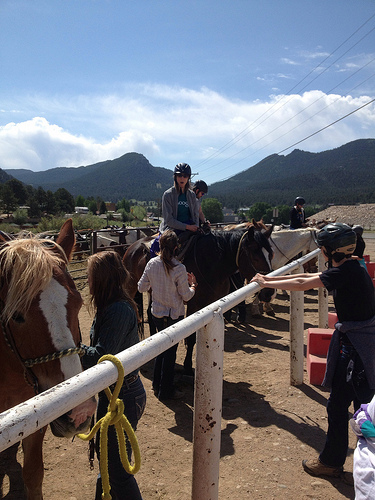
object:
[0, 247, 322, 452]
bar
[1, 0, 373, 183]
sky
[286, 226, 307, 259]
neck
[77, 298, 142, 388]
sweater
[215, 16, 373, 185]
power lines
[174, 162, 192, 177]
helmet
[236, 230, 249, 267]
harness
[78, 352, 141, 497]
rope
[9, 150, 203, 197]
mountain chain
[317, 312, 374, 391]
sweatshirt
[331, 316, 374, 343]
waist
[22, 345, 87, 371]
rope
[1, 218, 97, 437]
face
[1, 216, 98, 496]
horse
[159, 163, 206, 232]
woman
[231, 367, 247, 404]
rocks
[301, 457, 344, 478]
shoe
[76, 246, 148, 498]
lady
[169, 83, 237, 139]
cloud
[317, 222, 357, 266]
helmet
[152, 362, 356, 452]
shade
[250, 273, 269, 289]
hand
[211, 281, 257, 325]
rail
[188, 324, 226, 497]
pole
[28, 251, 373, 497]
ground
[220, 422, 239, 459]
shade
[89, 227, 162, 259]
fence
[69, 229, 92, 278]
gate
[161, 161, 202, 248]
person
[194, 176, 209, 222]
person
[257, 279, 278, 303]
nose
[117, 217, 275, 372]
horse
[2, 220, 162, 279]
kennel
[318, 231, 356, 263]
head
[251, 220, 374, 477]
boy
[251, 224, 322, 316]
horse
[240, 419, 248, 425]
rock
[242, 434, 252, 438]
rock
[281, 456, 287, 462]
rock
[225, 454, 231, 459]
rock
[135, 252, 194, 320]
shirt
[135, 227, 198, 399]
lady